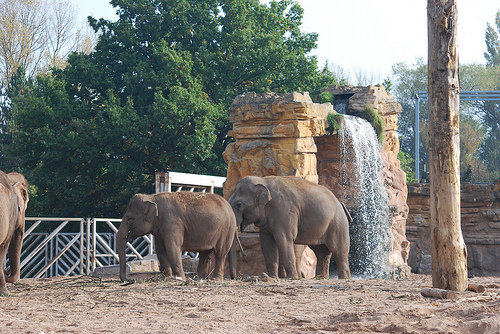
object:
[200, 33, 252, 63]
part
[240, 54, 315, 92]
branch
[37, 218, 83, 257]
part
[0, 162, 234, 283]
fence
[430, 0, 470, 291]
part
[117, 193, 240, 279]
elephant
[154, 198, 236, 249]
body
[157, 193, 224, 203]
back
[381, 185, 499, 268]
wall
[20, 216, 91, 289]
edge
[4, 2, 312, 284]
tree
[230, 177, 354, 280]
elephant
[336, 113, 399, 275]
water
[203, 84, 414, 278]
structure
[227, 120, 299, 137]
rock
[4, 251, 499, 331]
ground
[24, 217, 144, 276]
fencing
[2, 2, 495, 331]
enclosure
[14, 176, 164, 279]
doors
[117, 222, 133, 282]
trunk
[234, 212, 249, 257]
tail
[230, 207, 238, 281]
trunk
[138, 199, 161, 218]
ear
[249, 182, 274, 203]
ear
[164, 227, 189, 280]
leg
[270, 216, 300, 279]
leg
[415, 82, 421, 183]
part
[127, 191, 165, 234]
part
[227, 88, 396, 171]
part